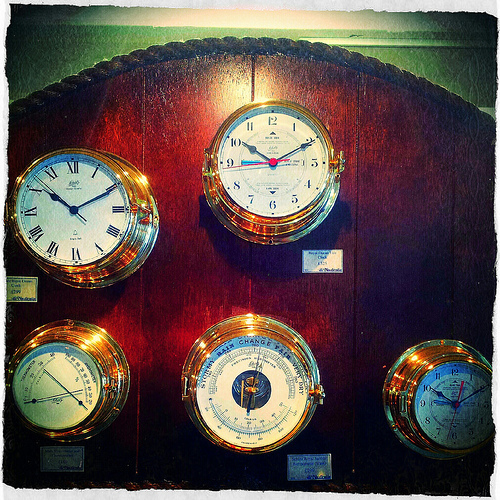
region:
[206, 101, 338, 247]
A clock on the wall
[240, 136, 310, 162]
The hands on the clock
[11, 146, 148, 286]
Roman numerals on the clock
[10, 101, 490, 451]
Clocks on the wall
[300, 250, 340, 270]
A card below the clock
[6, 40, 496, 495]
A wall behind the clocks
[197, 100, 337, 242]
The clock is showing the time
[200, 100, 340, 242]
The clock is circular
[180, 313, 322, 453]
A time telling device below the analog clock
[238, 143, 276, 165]
The hour hand on the clock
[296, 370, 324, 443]
edge of a clock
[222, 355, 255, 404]
part of a hand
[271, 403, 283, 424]
part of a glass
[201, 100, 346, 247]
the clock on the wall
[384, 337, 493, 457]
the clock on the wall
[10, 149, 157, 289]
the clock on the wall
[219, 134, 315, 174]
the hands on the clock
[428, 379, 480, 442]
the hands on the clock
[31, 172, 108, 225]
the hands on the clock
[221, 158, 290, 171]
the seconds hand on the clock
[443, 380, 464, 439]
the seconds hand on the clock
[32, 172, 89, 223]
the seconds hand on the clock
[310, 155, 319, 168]
the number 3 on the clock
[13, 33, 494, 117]
rope shape on curved wood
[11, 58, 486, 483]
panels of dark wood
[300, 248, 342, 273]
white label with words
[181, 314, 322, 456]
brass frame on gauge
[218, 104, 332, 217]
clock with white face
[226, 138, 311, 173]
black and red clock hands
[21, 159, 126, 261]
roman numerals on clock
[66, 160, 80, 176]
roman numeral number twelve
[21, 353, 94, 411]
gauge with two arches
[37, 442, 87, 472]
label with border inside